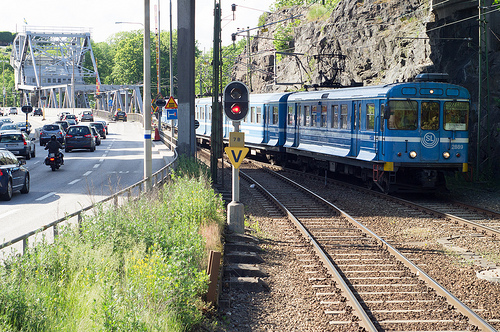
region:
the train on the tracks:
[178, 67, 494, 174]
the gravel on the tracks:
[270, 193, 310, 330]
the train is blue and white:
[178, 70, 462, 183]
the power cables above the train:
[241, 6, 452, 68]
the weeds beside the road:
[139, 180, 186, 329]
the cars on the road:
[3, 112, 140, 210]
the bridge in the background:
[13, 34, 145, 127]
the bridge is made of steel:
[13, 37, 120, 114]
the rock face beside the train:
[261, 14, 486, 69]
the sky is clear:
[59, 7, 126, 29]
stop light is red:
[221, 96, 246, 123]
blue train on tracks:
[155, 71, 486, 205]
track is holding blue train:
[253, 150, 498, 245]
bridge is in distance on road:
[6, 30, 157, 127]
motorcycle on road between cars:
[36, 128, 71, 174]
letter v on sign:
[221, 142, 251, 172]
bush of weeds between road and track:
[2, 152, 228, 327]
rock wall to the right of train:
[227, 1, 499, 191]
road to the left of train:
[5, 105, 185, 269]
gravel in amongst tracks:
[197, 131, 499, 328]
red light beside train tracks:
[214, 73, 264, 218]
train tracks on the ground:
[245, 153, 413, 324]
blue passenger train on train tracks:
[281, 76, 488, 178]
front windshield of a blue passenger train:
[383, 98, 466, 132]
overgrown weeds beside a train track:
[65, 169, 209, 324]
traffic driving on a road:
[7, 96, 112, 190]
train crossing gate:
[150, 1, 170, 143]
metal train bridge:
[18, 32, 155, 124]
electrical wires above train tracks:
[236, 1, 476, 71]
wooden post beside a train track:
[197, 239, 231, 310]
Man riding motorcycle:
[40, 132, 65, 171]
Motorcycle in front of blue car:
[38, 135, 73, 175]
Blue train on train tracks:
[160, 80, 477, 195]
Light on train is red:
[407, 150, 417, 160]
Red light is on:
[230, 104, 240, 116]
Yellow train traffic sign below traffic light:
[225, 144, 249, 166]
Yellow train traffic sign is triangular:
[222, 142, 252, 167]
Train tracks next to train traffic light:
[198, 140, 495, 330]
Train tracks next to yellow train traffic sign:
[199, 145, 488, 329]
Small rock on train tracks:
[375, 313, 385, 318]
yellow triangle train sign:
[210, 139, 258, 172]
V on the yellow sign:
[224, 139, 260, 173]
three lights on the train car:
[394, 79, 478, 168]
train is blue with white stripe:
[307, 94, 438, 170]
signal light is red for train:
[204, 79, 271, 126]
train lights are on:
[378, 79, 487, 170]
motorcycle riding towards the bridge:
[35, 135, 83, 172]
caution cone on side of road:
[146, 125, 170, 146]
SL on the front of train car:
[420, 127, 440, 149]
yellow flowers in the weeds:
[22, 242, 209, 311]